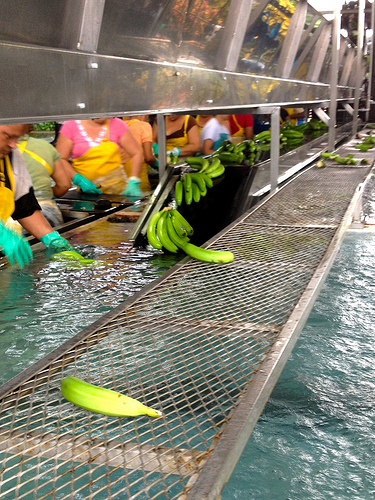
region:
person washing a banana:
[0, 121, 79, 276]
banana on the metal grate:
[54, 370, 178, 434]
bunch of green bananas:
[143, 199, 243, 271]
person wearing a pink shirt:
[65, 120, 129, 156]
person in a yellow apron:
[158, 117, 203, 154]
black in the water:
[275, 389, 318, 431]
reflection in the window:
[245, 11, 292, 71]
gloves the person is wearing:
[39, 231, 78, 254]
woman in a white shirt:
[199, 115, 228, 153]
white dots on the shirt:
[76, 122, 88, 140]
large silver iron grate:
[139, 287, 299, 366]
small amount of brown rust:
[197, 436, 223, 461]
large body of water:
[323, 275, 362, 425]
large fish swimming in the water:
[155, 363, 317, 438]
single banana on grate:
[29, 370, 150, 428]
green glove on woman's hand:
[31, 227, 74, 256]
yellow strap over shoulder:
[18, 140, 58, 180]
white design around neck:
[69, 120, 112, 156]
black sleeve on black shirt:
[4, 187, 43, 221]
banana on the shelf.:
[56, 366, 161, 428]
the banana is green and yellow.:
[56, 369, 165, 419]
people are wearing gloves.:
[0, 217, 78, 264]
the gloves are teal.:
[0, 217, 76, 267]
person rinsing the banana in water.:
[50, 235, 98, 268]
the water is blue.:
[223, 172, 371, 495]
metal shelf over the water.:
[3, 188, 355, 499]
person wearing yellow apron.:
[75, 140, 128, 196]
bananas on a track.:
[142, 119, 322, 254]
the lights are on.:
[304, 0, 369, 50]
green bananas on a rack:
[146, 195, 237, 268]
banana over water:
[53, 359, 159, 420]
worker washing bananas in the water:
[28, 212, 98, 275]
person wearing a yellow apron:
[80, 142, 128, 197]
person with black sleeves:
[13, 185, 48, 225]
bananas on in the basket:
[182, 144, 216, 208]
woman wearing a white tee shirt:
[199, 122, 233, 145]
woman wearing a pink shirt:
[66, 117, 136, 157]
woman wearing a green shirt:
[23, 145, 68, 198]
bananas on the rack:
[315, 140, 374, 178]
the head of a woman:
[3, 120, 36, 165]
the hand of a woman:
[1, 185, 76, 267]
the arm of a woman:
[18, 144, 87, 252]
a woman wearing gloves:
[4, 219, 34, 270]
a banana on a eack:
[72, 360, 157, 453]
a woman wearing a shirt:
[65, 97, 146, 165]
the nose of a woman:
[4, 134, 24, 154]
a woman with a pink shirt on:
[52, 107, 149, 178]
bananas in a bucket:
[141, 140, 312, 260]